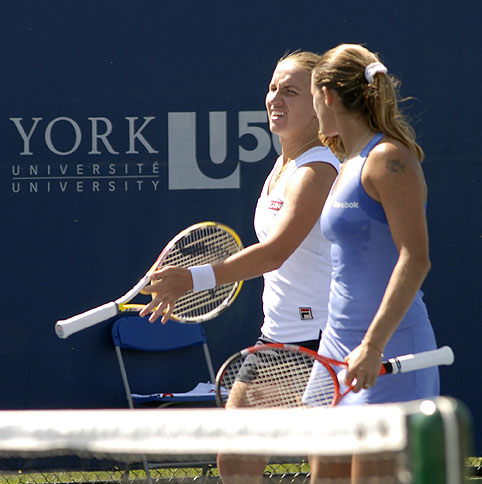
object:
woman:
[299, 44, 441, 483]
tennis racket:
[213, 343, 455, 411]